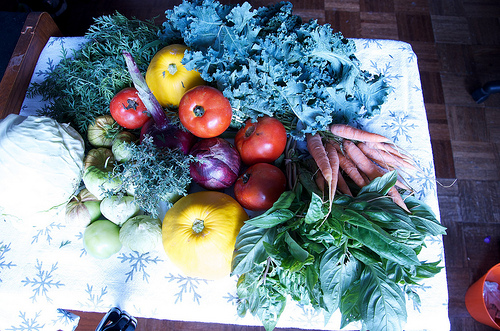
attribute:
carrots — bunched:
[267, 96, 420, 190]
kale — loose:
[205, 19, 385, 130]